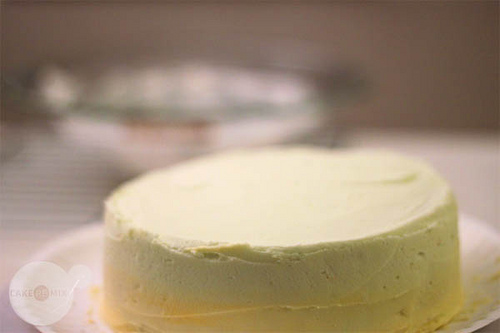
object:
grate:
[5, 93, 145, 234]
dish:
[6, 213, 500, 332]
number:
[9, 284, 70, 302]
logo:
[9, 257, 82, 326]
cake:
[97, 146, 465, 333]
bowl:
[31, 56, 372, 178]